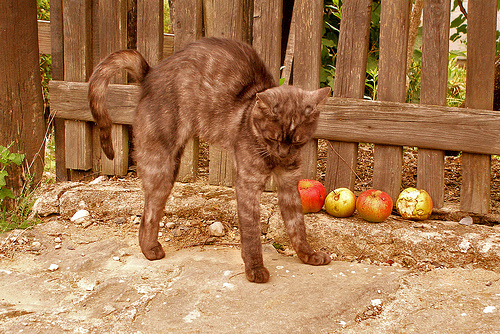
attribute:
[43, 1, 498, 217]
fence — brown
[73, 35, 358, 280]
cat — Brown 